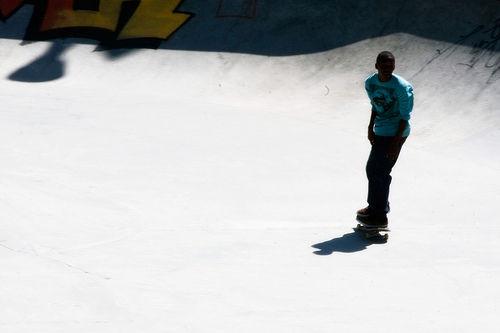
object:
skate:
[357, 219, 393, 245]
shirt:
[363, 72, 415, 138]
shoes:
[355, 209, 391, 228]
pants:
[364, 122, 409, 215]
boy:
[354, 48, 416, 230]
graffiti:
[0, 0, 197, 52]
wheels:
[364, 232, 376, 238]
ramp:
[0, 0, 500, 283]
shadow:
[5, 37, 74, 84]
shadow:
[98, 42, 134, 62]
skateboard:
[357, 215, 393, 241]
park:
[0, 2, 500, 332]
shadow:
[307, 228, 376, 259]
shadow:
[0, 0, 500, 59]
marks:
[432, 50, 488, 127]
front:
[342, 202, 373, 257]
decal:
[372, 91, 400, 120]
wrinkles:
[395, 83, 418, 125]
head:
[372, 50, 400, 80]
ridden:
[354, 203, 394, 242]